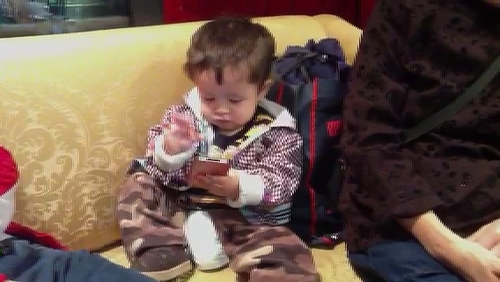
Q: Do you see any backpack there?
A: Yes, there is a backpack.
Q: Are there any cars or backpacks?
A: Yes, there is a backpack.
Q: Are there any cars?
A: No, there are no cars.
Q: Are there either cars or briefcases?
A: No, there are no cars or briefcases.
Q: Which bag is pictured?
A: The bag is a backpack.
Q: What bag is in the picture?
A: The bag is a backpack.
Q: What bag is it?
A: The bag is a backpack.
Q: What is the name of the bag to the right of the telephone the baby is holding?
A: The bag is a backpack.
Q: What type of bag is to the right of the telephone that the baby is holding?
A: The bag is a backpack.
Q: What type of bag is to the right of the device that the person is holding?
A: The bag is a backpack.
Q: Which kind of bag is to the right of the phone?
A: The bag is a backpack.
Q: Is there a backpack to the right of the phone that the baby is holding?
A: Yes, there is a backpack to the right of the phone.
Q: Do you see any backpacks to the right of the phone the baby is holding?
A: Yes, there is a backpack to the right of the phone.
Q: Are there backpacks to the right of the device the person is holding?
A: Yes, there is a backpack to the right of the phone.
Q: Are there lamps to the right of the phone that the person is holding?
A: No, there is a backpack to the right of the telephone.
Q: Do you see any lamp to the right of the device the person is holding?
A: No, there is a backpack to the right of the telephone.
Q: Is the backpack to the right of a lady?
A: No, the backpack is to the right of a phone.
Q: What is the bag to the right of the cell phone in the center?
A: The bag is a backpack.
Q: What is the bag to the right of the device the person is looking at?
A: The bag is a backpack.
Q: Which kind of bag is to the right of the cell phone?
A: The bag is a backpack.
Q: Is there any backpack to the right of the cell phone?
A: Yes, there is a backpack to the right of the cell phone.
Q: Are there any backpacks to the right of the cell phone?
A: Yes, there is a backpack to the right of the cell phone.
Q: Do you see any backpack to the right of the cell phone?
A: Yes, there is a backpack to the right of the cell phone.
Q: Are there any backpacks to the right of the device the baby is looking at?
A: Yes, there is a backpack to the right of the cell phone.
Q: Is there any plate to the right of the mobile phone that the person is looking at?
A: No, there is a backpack to the right of the cellphone.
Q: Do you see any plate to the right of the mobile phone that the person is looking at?
A: No, there is a backpack to the right of the cellphone.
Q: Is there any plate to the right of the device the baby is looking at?
A: No, there is a backpack to the right of the cellphone.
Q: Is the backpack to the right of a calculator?
A: No, the backpack is to the right of a cell phone.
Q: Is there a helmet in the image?
A: No, there are no helmets.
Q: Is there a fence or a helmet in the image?
A: No, there are no helmets or fences.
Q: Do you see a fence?
A: No, there are no fences.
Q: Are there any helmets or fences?
A: No, there are no fences or helmets.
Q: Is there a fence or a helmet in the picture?
A: No, there are no fences or helmets.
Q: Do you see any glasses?
A: No, there are no glasses.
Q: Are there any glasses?
A: No, there are no glasses.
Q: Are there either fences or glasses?
A: No, there are no glasses or fences.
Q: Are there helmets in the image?
A: No, there are no helmets.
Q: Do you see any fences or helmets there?
A: No, there are no helmets or fences.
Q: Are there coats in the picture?
A: Yes, there is a coat.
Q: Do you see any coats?
A: Yes, there is a coat.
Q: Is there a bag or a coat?
A: Yes, there is a coat.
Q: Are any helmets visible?
A: No, there are no helmets.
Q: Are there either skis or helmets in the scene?
A: No, there are no helmets or skis.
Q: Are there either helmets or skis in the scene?
A: No, there are no helmets or skis.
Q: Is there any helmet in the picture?
A: No, there are no helmets.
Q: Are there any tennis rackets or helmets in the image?
A: No, there are no helmets or tennis rackets.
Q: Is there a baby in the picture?
A: Yes, there is a baby.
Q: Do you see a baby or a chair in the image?
A: Yes, there is a baby.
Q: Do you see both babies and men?
A: No, there is a baby but no men.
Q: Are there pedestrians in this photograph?
A: No, there are no pedestrians.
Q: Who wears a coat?
A: The baby wears a coat.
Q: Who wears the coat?
A: The baby wears a coat.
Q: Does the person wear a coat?
A: Yes, the baby wears a coat.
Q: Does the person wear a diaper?
A: No, the baby wears a coat.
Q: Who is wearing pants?
A: The baby is wearing pants.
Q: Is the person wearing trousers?
A: Yes, the baby is wearing trousers.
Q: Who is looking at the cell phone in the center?
A: The baby is looking at the cellphone.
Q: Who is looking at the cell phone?
A: The baby is looking at the cellphone.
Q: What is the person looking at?
A: The baby is looking at the cellphone.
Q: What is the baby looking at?
A: The baby is looking at the cellphone.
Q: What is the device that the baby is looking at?
A: The device is a cell phone.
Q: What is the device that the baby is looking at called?
A: The device is a cell phone.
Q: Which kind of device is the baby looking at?
A: The baby is looking at the cell phone.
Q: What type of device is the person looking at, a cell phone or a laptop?
A: The baby is looking at a cell phone.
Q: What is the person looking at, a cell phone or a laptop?
A: The baby is looking at a cell phone.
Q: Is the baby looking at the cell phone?
A: Yes, the baby is looking at the cell phone.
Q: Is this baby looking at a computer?
A: No, the baby is looking at the cell phone.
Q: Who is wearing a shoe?
A: The baby is wearing a shoe.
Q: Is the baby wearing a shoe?
A: Yes, the baby is wearing a shoe.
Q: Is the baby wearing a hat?
A: No, the baby is wearing a shoe.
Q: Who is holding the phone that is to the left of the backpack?
A: The baby is holding the telephone.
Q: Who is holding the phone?
A: The baby is holding the telephone.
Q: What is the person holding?
A: The baby is holding the telephone.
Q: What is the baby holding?
A: The baby is holding the telephone.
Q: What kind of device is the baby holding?
A: The baby is holding the telephone.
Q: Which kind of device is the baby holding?
A: The baby is holding the telephone.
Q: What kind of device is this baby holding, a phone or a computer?
A: The baby is holding a phone.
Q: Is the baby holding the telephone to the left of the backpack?
A: Yes, the baby is holding the telephone.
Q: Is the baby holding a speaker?
A: No, the baby is holding the telephone.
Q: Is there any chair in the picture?
A: Yes, there is a chair.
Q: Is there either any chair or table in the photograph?
A: Yes, there is a chair.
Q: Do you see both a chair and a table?
A: No, there is a chair but no tables.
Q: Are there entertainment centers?
A: No, there are no entertainment centers.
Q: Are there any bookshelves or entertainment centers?
A: No, there are no entertainment centers or bookshelves.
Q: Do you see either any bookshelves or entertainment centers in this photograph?
A: No, there are no entertainment centers or bookshelves.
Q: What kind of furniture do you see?
A: The furniture is a chair.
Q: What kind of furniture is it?
A: The piece of furniture is a chair.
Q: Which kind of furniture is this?
A: This is a chair.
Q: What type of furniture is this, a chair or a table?
A: This is a chair.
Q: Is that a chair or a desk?
A: That is a chair.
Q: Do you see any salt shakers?
A: No, there are no salt shakers.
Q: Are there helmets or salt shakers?
A: No, there are no salt shakers or helmets.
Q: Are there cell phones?
A: Yes, there is a cell phone.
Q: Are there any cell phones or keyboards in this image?
A: Yes, there is a cell phone.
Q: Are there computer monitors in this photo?
A: No, there are no computer monitors.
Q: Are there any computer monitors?
A: No, there are no computer monitors.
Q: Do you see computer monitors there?
A: No, there are no computer monitors.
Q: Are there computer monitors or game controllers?
A: No, there are no computer monitors or game controllers.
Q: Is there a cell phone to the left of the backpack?
A: Yes, there is a cell phone to the left of the backpack.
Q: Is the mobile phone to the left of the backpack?
A: Yes, the mobile phone is to the left of the backpack.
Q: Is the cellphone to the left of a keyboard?
A: No, the cellphone is to the left of the backpack.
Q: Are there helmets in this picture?
A: No, there are no helmets.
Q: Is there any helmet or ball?
A: No, there are no helmets or balls.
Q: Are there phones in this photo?
A: Yes, there is a phone.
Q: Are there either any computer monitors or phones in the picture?
A: Yes, there is a phone.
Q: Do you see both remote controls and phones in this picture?
A: No, there is a phone but no remote controls.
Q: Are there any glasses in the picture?
A: No, there are no glasses.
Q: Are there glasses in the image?
A: No, there are no glasses.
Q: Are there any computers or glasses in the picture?
A: No, there are no glasses or computers.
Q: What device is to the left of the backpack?
A: The device is a phone.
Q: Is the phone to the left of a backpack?
A: Yes, the phone is to the left of a backpack.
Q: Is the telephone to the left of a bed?
A: No, the telephone is to the left of a backpack.